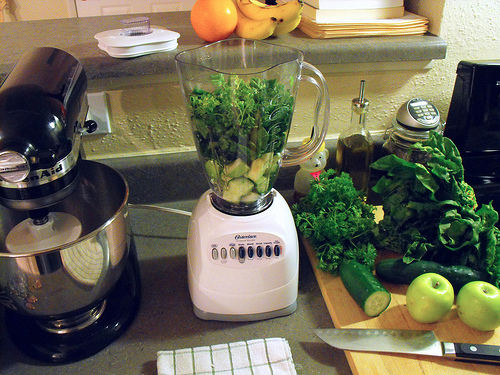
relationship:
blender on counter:
[175, 33, 335, 327] [3, 129, 497, 371]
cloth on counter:
[153, 325, 302, 373] [3, 129, 497, 371]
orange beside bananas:
[190, 2, 237, 44] [239, 1, 311, 40]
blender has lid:
[175, 33, 335, 327] [96, 15, 186, 64]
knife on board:
[309, 321, 499, 369] [302, 191, 499, 369]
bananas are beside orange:
[239, 1, 311, 40] [190, 2, 237, 44]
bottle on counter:
[335, 78, 375, 201] [3, 129, 497, 371]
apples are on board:
[402, 269, 499, 335] [302, 191, 499, 369]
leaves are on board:
[294, 161, 395, 275] [302, 191, 499, 369]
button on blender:
[273, 244, 283, 259] [175, 33, 335, 327]